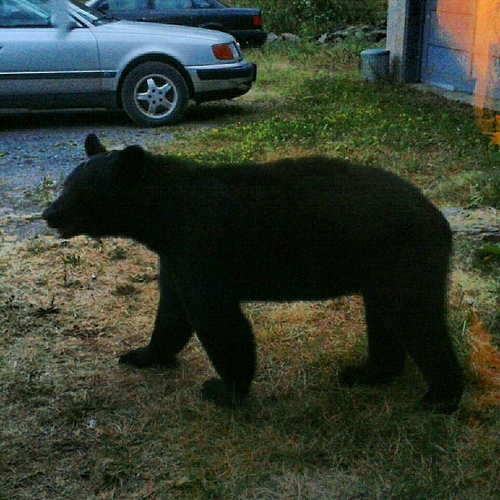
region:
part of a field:
[313, 457, 322, 474]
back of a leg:
[225, 350, 236, 380]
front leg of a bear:
[166, 326, 186, 343]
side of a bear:
[266, 260, 274, 272]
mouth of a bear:
[69, 207, 77, 217]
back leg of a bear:
[371, 366, 376, 373]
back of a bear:
[433, 231, 434, 242]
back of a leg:
[238, 358, 241, 362]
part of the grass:
[458, 416, 474, 446]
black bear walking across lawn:
[27, 123, 472, 430]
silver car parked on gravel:
[0, 1, 262, 133]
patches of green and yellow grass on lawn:
[12, 241, 131, 363]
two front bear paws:
[110, 337, 270, 409]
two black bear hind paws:
[333, 341, 472, 421]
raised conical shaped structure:
[349, 41, 394, 86]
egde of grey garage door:
[383, 1, 498, 113]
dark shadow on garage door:
[401, 2, 491, 107]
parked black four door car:
[80, 1, 269, 52]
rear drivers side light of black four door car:
[247, 10, 267, 31]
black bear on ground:
[32, 128, 470, 453]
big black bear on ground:
[31, 138, 470, 450]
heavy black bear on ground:
[43, 135, 467, 435]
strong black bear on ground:
[35, 127, 472, 441]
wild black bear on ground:
[41, 130, 468, 440]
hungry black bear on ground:
[33, 134, 468, 435]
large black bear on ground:
[22, 129, 468, 443]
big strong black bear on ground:
[36, 128, 473, 449]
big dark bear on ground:
[33, 133, 466, 444]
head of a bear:
[40, 127, 137, 263]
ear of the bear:
[110, 134, 160, 192]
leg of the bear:
[188, 286, 293, 415]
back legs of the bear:
[335, 290, 465, 415]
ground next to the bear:
[71, 384, 159, 465]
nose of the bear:
[33, 188, 88, 238]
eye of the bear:
[63, 178, 109, 220]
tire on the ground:
[118, 54, 195, 131]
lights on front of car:
[202, 29, 266, 89]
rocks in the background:
[316, 18, 372, 48]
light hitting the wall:
[428, 9, 491, 63]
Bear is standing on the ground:
[41, 131, 472, 416]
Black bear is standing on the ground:
[42, 129, 474, 414]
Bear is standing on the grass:
[39, 127, 474, 414]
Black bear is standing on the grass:
[43, 128, 468, 417]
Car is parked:
[0, 4, 265, 126]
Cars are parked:
[0, 0, 274, 131]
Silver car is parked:
[1, 3, 262, 124]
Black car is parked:
[69, 0, 269, 53]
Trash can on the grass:
[356, 40, 398, 90]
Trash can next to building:
[357, 43, 397, 88]